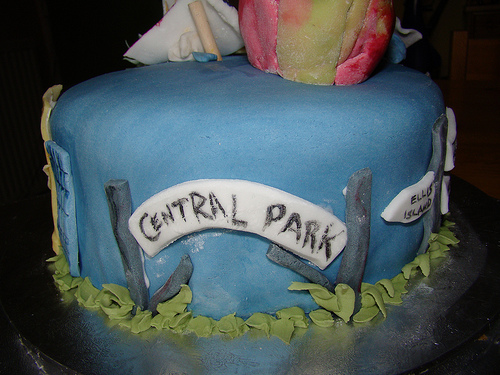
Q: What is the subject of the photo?
A: Cake.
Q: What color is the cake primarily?
A: Blue.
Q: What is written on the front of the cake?
A: Central Park.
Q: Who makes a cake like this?
A: Baker.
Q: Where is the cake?
A: On a platter.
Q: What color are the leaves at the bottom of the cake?
A: Green.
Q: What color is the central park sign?
A: White.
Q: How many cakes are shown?
A: One.